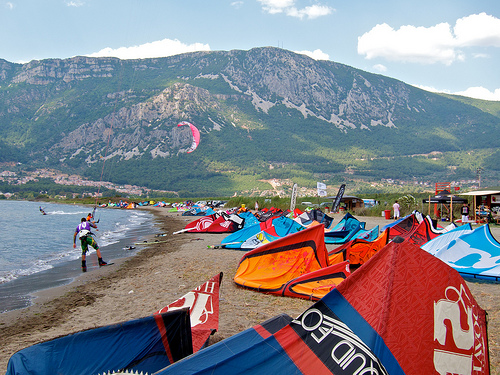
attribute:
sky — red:
[9, 3, 481, 83]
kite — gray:
[157, 101, 216, 175]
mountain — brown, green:
[36, 34, 447, 164]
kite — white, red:
[169, 212, 239, 249]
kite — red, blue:
[222, 206, 303, 259]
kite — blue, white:
[415, 206, 484, 277]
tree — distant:
[153, 149, 167, 176]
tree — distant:
[270, 102, 286, 122]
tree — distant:
[321, 114, 331, 137]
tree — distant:
[255, 124, 271, 151]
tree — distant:
[255, 124, 276, 149]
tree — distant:
[142, 156, 160, 185]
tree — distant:
[204, 129, 216, 154]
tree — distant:
[110, 149, 131, 176]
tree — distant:
[412, 134, 426, 159]